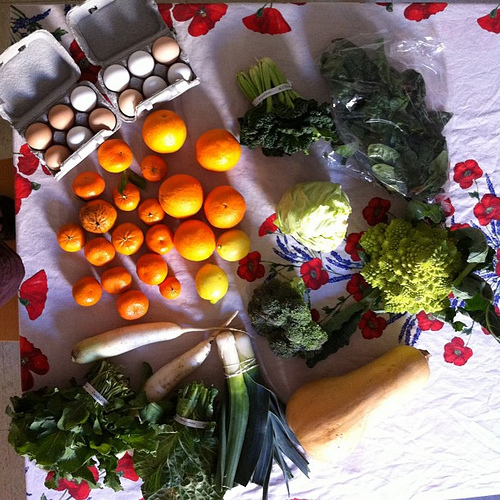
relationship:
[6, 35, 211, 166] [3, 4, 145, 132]
eggs in paper cartons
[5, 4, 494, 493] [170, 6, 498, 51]
tablecloth has red poppy pattern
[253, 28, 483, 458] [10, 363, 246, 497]
vegetables has green leafy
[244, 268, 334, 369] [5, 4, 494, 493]
broccoli on table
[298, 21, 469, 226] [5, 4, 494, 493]
lettuce on table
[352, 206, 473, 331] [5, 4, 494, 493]
squash on table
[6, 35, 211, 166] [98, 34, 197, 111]
eggs in a half dozen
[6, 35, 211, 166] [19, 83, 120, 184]
eggs in a half a dozen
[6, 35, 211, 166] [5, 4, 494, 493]
eggs are on table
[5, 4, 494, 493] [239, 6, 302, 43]
tablecloth has red flowers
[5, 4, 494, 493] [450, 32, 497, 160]
tablecloth has wrinkles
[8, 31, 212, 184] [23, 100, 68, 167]
carton color brown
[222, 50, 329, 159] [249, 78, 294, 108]
herbs with twist ties